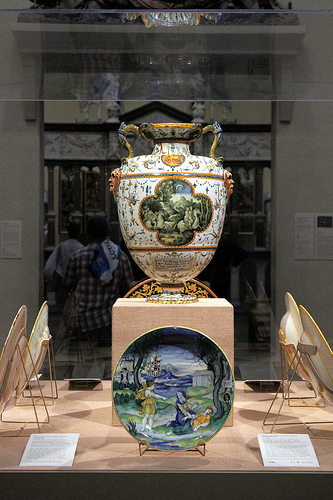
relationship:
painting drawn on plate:
[119, 339, 223, 445] [110, 323, 235, 455]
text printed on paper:
[23, 432, 69, 463] [6, 428, 81, 470]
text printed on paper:
[260, 433, 314, 463] [253, 424, 324, 468]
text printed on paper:
[23, 432, 69, 463] [17, 428, 81, 470]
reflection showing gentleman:
[56, 217, 135, 340] [62, 216, 143, 357]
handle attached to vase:
[200, 120, 229, 173] [106, 112, 240, 307]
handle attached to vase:
[114, 114, 140, 158] [106, 112, 240, 307]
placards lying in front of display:
[16, 424, 78, 467] [1, 97, 323, 472]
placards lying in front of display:
[253, 423, 323, 470] [1, 97, 323, 472]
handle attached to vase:
[200, 120, 226, 166] [106, 112, 240, 307]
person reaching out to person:
[165, 390, 195, 425] [166, 406, 212, 436]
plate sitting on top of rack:
[110, 323, 235, 455] [136, 437, 206, 456]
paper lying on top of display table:
[255, 433, 322, 467] [0, 377, 332, 468]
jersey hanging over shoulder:
[89, 239, 121, 285] [95, 243, 131, 265]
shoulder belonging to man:
[95, 243, 131, 265] [60, 214, 134, 345]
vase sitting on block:
[108, 102, 239, 308] [112, 295, 236, 428]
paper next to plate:
[19, 432, 79, 466] [110, 323, 235, 455]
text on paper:
[263, 433, 311, 458] [253, 430, 320, 469]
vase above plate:
[92, 102, 244, 308] [110, 323, 235, 455]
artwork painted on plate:
[111, 324, 236, 457] [110, 323, 235, 455]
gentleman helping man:
[59, 216, 143, 380] [42, 217, 86, 319]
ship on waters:
[144, 354, 162, 377] [146, 371, 190, 391]